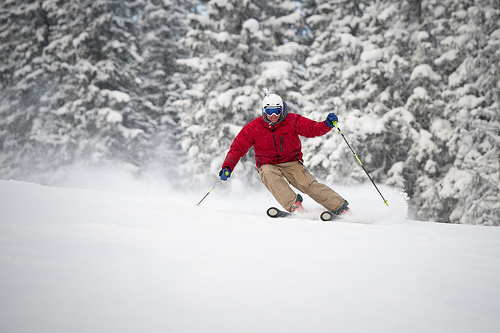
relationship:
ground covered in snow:
[16, 221, 468, 325] [7, 210, 486, 323]